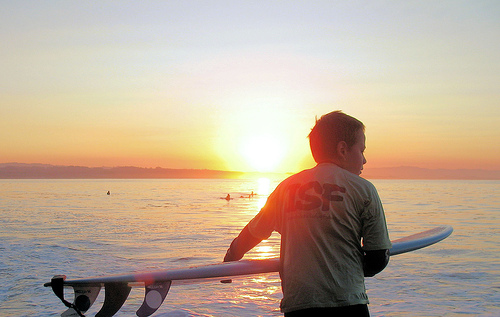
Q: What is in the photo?
A: A boy.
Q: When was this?
A: Daytime.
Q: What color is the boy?
A: White.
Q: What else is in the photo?
A: Water.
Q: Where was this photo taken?
A: At the beach.